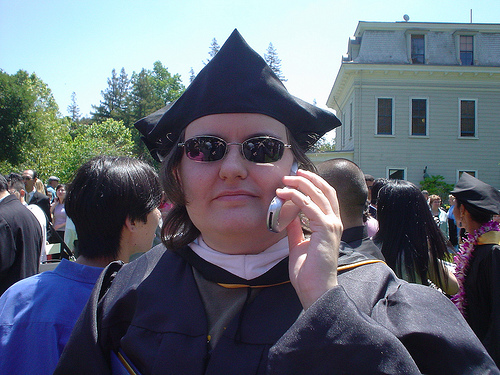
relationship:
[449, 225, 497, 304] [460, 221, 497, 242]
lae around neck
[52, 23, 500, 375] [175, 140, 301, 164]
person wearing sunglasses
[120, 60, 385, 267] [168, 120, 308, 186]
person wearing sunglasses